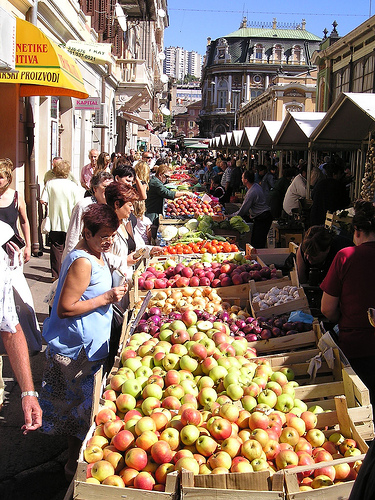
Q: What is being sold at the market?
A: Fruit and vegetables.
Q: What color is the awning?
A: Yellow.